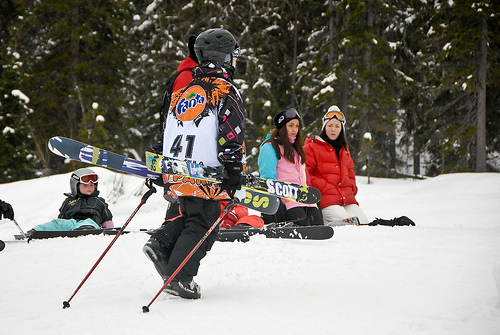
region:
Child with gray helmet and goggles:
[19, 167, 131, 244]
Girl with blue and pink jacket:
[256, 105, 323, 227]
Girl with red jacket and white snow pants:
[303, 108, 400, 228]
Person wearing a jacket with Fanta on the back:
[140, 28, 255, 303]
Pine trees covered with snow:
[6, 3, 495, 184]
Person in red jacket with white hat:
[161, 26, 201, 131]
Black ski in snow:
[139, 220, 338, 243]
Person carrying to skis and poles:
[43, 26, 320, 312]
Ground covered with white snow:
[1, 163, 499, 330]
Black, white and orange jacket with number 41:
[151, 65, 248, 198]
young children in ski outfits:
[2, 23, 363, 315]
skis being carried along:
[43, 135, 323, 215]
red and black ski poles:
[61, 185, 234, 315]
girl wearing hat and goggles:
[318, 103, 350, 144]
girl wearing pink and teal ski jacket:
[255, 106, 317, 211]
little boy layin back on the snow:
[29, 167, 114, 240]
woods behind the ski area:
[0, 0, 498, 184]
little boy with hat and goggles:
[68, 166, 100, 196]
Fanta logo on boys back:
[173, 83, 208, 123]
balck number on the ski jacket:
[168, 131, 198, 161]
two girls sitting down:
[253, 94, 411, 229]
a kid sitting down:
[31, 168, 116, 233]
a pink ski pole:
[139, 201, 249, 316]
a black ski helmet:
[188, 28, 241, 68]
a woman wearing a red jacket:
[303, 103, 370, 206]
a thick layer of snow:
[239, 248, 486, 328]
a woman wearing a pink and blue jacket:
[256, 105, 318, 211]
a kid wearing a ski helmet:
[63, 168, 103, 199]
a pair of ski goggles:
[73, 170, 103, 186]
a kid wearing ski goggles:
[69, 170, 97, 197]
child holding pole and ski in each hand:
[41, 27, 322, 317]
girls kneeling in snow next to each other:
[257, 100, 363, 225]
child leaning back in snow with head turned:
[27, 161, 117, 241]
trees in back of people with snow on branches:
[2, 11, 492, 176]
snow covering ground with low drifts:
[7, 160, 492, 326]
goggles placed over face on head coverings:
[270, 101, 350, 121]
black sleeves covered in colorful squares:
[157, 67, 242, 178]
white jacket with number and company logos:
[155, 66, 225, 201]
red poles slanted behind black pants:
[57, 180, 252, 311]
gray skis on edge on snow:
[210, 220, 335, 241]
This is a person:
[312, 93, 378, 248]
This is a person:
[256, 81, 314, 261]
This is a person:
[140, 21, 250, 301]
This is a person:
[15, 148, 131, 259]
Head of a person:
[317, 96, 357, 141]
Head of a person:
[274, 97, 312, 145]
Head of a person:
[181, 23, 246, 79]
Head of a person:
[59, 160, 111, 199]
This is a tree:
[465, 5, 498, 176]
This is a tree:
[353, 9, 379, 184]